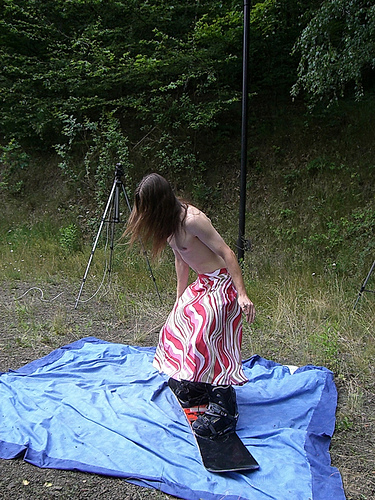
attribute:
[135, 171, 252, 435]
man — long-haired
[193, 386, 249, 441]
foot — man's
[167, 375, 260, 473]
snowboard — black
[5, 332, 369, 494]
blanket — blue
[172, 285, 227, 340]
skirt — long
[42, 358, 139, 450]
back ground — white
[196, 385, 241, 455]
boot — snowboard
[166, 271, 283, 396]
half — lower, man's